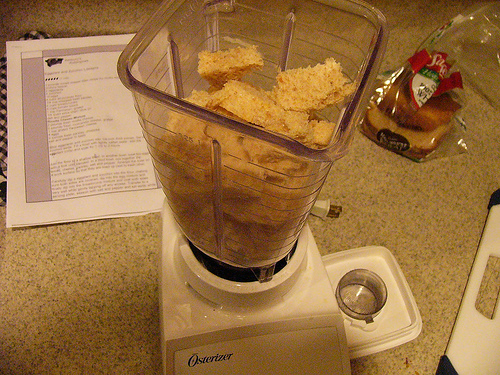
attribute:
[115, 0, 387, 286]
jar — plastice, clear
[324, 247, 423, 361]
top — white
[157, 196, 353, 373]
blender — white, for food, sitting, motor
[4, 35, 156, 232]
sheet — paper, pf, recipe, book, paperwork, black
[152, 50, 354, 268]
bread — cut, crumbs, food, brown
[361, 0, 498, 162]
bag — plastice, open, red, green, white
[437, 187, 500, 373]
board — white, kitchen tool, black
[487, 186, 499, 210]
corner — black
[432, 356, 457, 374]
corner — black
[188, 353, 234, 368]
logo — blue, writing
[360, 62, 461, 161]
bread — open, loaf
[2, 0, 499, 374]
counter — speckled, grey, black, white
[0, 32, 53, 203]
cloth — checkered, blue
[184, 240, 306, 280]
ring — black